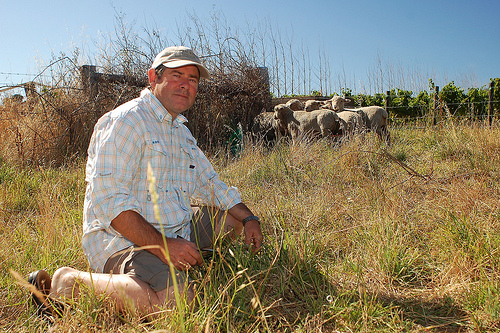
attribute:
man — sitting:
[12, 55, 273, 332]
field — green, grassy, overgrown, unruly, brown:
[4, 107, 496, 332]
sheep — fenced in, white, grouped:
[250, 83, 383, 151]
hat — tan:
[147, 42, 208, 72]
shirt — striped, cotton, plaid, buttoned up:
[88, 95, 236, 272]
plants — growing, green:
[282, 85, 499, 129]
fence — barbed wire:
[0, 63, 499, 114]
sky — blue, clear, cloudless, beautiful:
[1, 2, 498, 102]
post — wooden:
[84, 63, 103, 114]